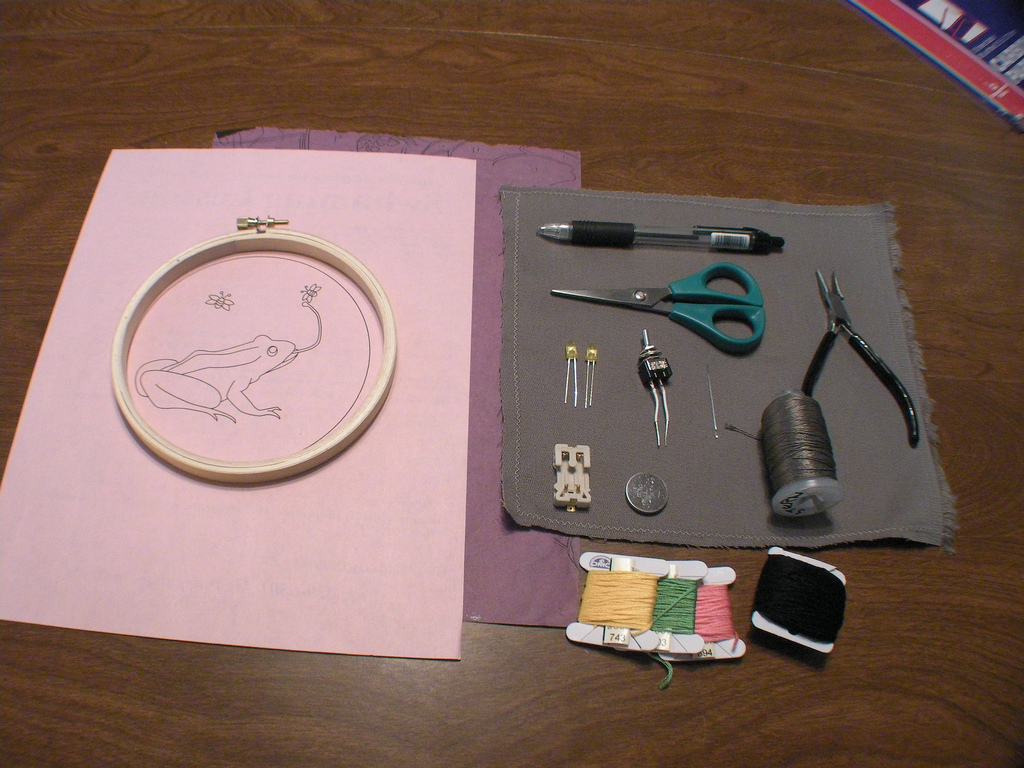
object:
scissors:
[552, 262, 766, 354]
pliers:
[801, 269, 919, 450]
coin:
[625, 471, 669, 512]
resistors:
[565, 340, 599, 409]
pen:
[536, 220, 786, 256]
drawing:
[124, 256, 369, 464]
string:
[565, 547, 847, 691]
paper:
[0, 144, 476, 660]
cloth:
[497, 184, 957, 555]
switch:
[637, 328, 674, 446]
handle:
[801, 331, 920, 449]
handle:
[668, 261, 767, 354]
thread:
[751, 547, 846, 655]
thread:
[565, 552, 669, 652]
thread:
[651, 560, 708, 654]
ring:
[110, 228, 398, 482]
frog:
[134, 301, 322, 423]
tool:
[110, 215, 398, 483]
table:
[0, 0, 1024, 768]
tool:
[706, 365, 719, 439]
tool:
[585, 343, 599, 408]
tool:
[564, 341, 579, 408]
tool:
[552, 443, 591, 512]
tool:
[725, 388, 845, 518]